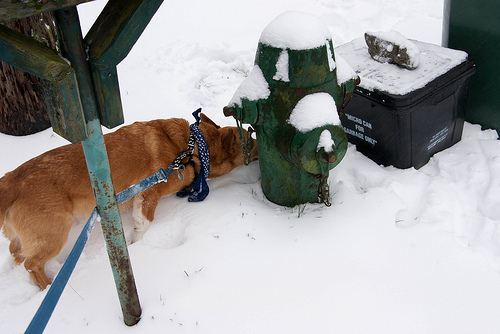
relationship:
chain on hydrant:
[316, 154, 336, 210] [220, 25, 371, 211]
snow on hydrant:
[255, 8, 341, 45] [220, 25, 371, 211]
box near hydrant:
[343, 33, 479, 174] [220, 25, 371, 211]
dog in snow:
[3, 109, 270, 294] [10, 187, 314, 330]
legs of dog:
[10, 235, 62, 294] [3, 109, 270, 294]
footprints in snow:
[358, 168, 454, 231] [10, 187, 314, 330]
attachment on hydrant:
[287, 114, 350, 174] [220, 25, 371, 211]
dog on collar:
[3, 109, 270, 294] [184, 116, 212, 206]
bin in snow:
[343, 33, 479, 174] [10, 187, 314, 330]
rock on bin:
[363, 28, 419, 70] [343, 33, 479, 174]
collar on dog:
[184, 123, 212, 208] [3, 109, 270, 294]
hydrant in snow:
[220, 25, 371, 211] [10, 187, 314, 330]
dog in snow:
[3, 109, 270, 294] [11, 175, 497, 333]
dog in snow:
[3, 109, 270, 294] [255, 8, 341, 45]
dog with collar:
[3, 109, 270, 294] [184, 123, 212, 208]